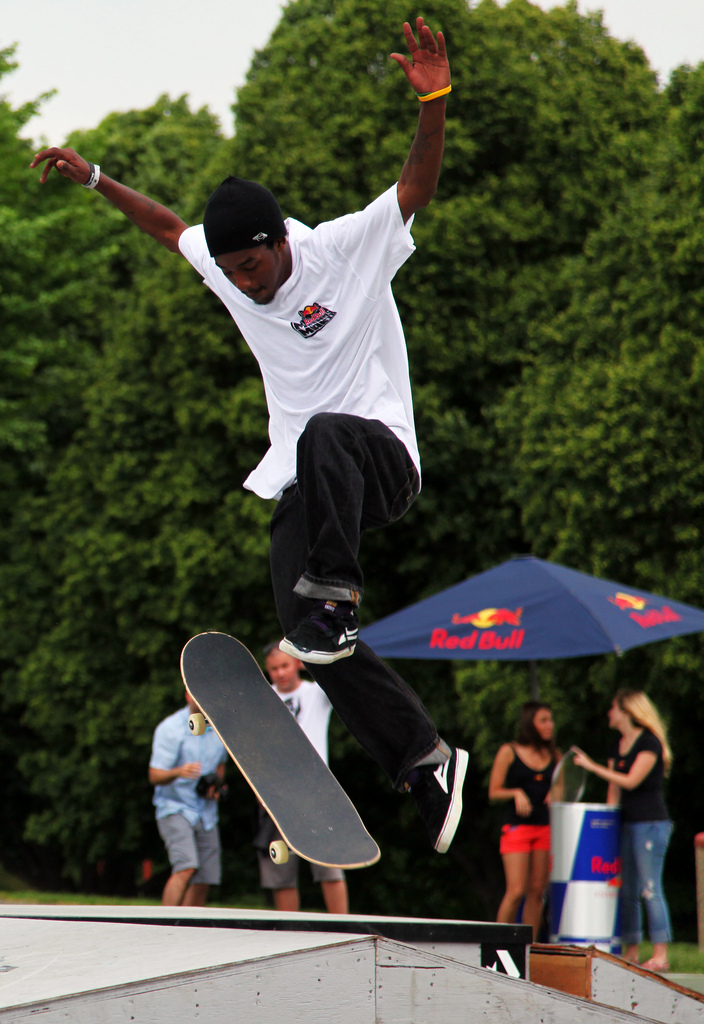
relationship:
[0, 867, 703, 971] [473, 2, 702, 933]
field has tree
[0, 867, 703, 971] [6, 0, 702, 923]
field has tree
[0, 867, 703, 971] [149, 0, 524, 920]
field has tree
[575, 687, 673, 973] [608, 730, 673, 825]
woman wearing a shirt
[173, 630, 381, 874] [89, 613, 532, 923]
skateboard in air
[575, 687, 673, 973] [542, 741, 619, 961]
woman next to cooler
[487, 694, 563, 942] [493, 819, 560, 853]
girl has red shorts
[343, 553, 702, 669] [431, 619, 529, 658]
umbrella has logo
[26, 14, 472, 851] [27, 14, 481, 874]
skater doing a trick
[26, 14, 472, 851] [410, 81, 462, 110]
person wearing bracelets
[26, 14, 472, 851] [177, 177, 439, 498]
man wearing a shirt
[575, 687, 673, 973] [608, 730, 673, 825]
woman wearing shirt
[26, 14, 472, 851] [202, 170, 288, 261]
person wearing hat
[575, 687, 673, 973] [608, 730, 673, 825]
woman wearing black top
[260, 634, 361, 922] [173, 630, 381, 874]
man behind skateboard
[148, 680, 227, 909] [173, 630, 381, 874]
man behind skateboard